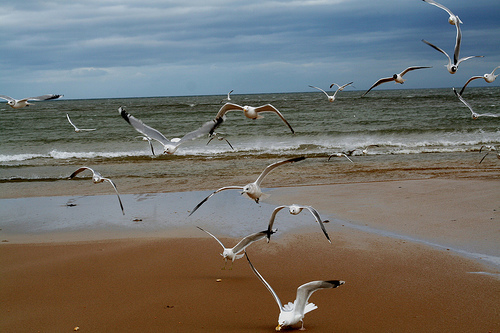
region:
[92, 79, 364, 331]
the birds are flying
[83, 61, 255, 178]
the birds are flying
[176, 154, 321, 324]
the birds are flying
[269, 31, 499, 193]
the birds are flying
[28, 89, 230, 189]
the birds are flying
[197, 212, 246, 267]
the bird is white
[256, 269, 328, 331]
the bird is white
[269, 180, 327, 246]
the bird is white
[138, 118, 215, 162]
the bird is white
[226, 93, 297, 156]
the bird is white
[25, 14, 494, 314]
this is on a beach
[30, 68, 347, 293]
This is a flock of seagulls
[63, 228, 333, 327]
The ground is sand here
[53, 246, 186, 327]
This sand is red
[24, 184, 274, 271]
This sand is wet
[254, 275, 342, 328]
The seagull is white and gray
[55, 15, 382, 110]
The sky is cloudy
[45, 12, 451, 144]
The clouds are gray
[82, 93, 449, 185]
The ocean is green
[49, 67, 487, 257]
This is along a coast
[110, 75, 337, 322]
these are birds flying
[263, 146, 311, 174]
this is the bird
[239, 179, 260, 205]
the bird is white in color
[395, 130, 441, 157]
the waves are on the sea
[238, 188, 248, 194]
the beak is sharp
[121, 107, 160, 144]
the wing is big in size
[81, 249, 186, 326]
the sand is brown in color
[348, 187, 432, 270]
the sand is wet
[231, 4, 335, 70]
the cloud is blue in color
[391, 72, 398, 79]
the head is black in color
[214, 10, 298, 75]
this is the sky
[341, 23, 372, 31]
the sky is blue in color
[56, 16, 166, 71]
the sky has some clouds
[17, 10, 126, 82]
the clouds are white in color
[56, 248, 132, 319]
this is the ground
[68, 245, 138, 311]
the ground is sandy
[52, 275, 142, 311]
the sand is brown in color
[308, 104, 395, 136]
this is some water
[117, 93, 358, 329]
these are some birds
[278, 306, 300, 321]
the feathers are white in color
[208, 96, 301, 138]
a bird in the sky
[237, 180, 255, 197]
the head of a bird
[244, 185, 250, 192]
the eye of a bird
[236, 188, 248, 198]
the beak of a bird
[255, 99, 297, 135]
the wing of a bird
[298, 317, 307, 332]
the leg of a bird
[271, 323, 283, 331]
the foot of a bird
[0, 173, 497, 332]
a sandy brown shore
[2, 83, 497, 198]
blue ocean waters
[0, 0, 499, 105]
a cloudy gray sky